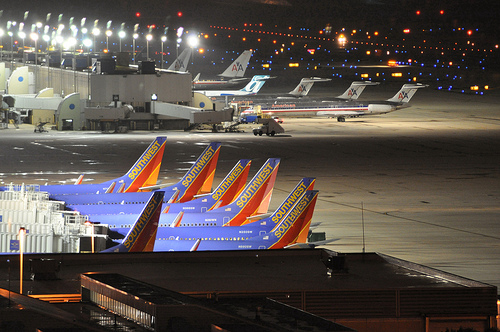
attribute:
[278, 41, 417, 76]
lights — colored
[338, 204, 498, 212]
line — yellow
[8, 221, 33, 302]
pole — white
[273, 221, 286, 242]
letter — yellow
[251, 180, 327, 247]
tail — plane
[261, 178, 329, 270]
tail — plane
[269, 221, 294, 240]
letter — yellow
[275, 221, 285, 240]
letter — yellow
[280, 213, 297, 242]
letter — yellow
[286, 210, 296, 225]
letter — yellow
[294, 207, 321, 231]
letter — yellow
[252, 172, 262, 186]
letter — yellow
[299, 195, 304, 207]
letter — yellow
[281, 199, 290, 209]
letter — yellow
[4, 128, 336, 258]
planes — lined up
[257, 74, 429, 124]
plane — silver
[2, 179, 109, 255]
gates — boarding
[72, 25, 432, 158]
airliners — six, American Airlines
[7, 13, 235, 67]
lights — bright, illuminated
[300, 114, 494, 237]
tarmac — grey, cement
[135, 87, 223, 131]
jetbridge — white, leading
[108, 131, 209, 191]
tail — yellow, red, orange